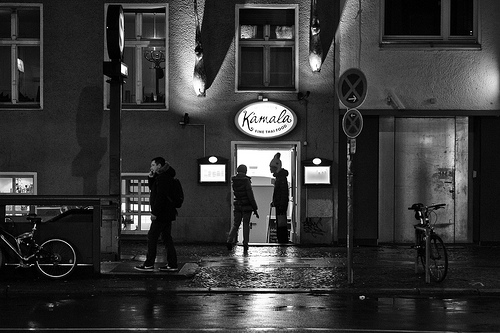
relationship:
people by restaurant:
[133, 149, 300, 251] [62, 67, 481, 280]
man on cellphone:
[140, 155, 197, 270] [150, 169, 154, 179]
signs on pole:
[335, 71, 367, 142] [343, 155, 366, 288]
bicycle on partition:
[7, 211, 99, 285] [39, 198, 131, 246]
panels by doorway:
[182, 147, 229, 204] [226, 139, 286, 241]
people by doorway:
[133, 149, 300, 251] [226, 139, 286, 241]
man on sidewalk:
[140, 155, 197, 270] [159, 246, 447, 294]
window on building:
[217, 8, 314, 95] [38, 37, 482, 233]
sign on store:
[235, 100, 302, 145] [47, 31, 465, 188]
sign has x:
[337, 65, 375, 113] [345, 77, 359, 102]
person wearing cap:
[266, 150, 303, 244] [273, 150, 283, 166]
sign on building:
[235, 100, 302, 145] [38, 37, 482, 233]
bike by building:
[402, 195, 455, 284] [38, 37, 482, 233]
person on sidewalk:
[266, 150, 303, 244] [159, 246, 447, 294]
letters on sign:
[248, 112, 287, 129] [235, 100, 302, 145]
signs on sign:
[335, 71, 367, 142] [337, 65, 375, 113]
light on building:
[179, 63, 210, 109] [38, 37, 482, 233]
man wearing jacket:
[140, 155, 197, 270] [149, 175, 179, 219]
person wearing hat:
[266, 150, 303, 244] [266, 152, 283, 167]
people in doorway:
[133, 149, 300, 251] [226, 139, 286, 241]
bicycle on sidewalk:
[7, 211, 99, 285] [159, 246, 447, 294]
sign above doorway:
[235, 100, 302, 145] [226, 139, 286, 241]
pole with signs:
[343, 155, 366, 288] [335, 71, 367, 142]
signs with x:
[335, 71, 367, 142] [345, 77, 359, 102]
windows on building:
[16, 15, 335, 96] [38, 37, 482, 233]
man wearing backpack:
[140, 155, 197, 270] [168, 172, 187, 211]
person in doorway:
[266, 150, 303, 244] [226, 139, 286, 241]